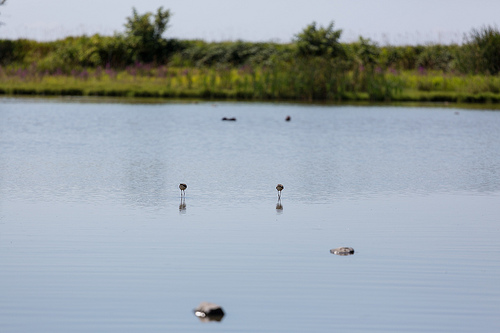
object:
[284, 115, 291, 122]
bird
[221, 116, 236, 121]
bird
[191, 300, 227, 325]
bird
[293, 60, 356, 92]
trees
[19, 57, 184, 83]
flowers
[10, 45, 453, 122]
bank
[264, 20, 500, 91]
bushes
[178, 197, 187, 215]
reflection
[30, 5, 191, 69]
bushes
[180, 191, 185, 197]
legs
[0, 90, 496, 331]
body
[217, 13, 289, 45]
body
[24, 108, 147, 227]
area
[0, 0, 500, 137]
background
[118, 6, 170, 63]
tree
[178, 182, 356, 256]
animals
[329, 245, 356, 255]
ducks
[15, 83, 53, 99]
rocks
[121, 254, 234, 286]
ripples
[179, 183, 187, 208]
bird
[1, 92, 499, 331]
water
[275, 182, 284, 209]
bird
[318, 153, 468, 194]
ripples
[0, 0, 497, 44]
sky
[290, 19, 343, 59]
trees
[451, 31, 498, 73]
trees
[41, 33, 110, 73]
trees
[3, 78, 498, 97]
grass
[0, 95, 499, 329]
lake